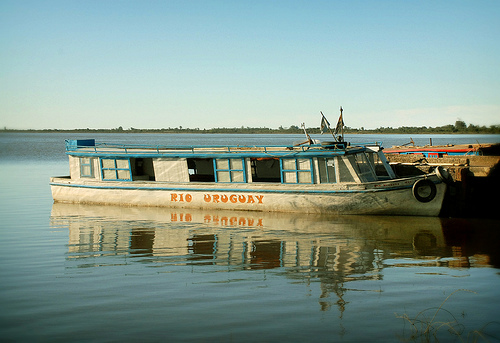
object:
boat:
[47, 139, 449, 214]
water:
[0, 133, 500, 343]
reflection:
[49, 203, 500, 327]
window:
[184, 158, 219, 183]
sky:
[0, 0, 499, 130]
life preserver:
[412, 177, 437, 203]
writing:
[169, 193, 263, 204]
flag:
[334, 105, 344, 143]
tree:
[454, 121, 468, 133]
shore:
[2, 133, 499, 142]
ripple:
[59, 244, 239, 265]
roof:
[382, 147, 480, 152]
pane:
[211, 158, 249, 184]